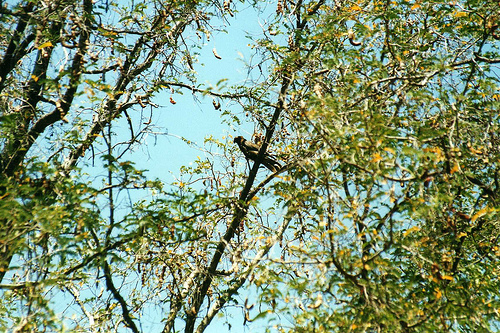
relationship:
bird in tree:
[233, 135, 283, 172] [3, 0, 497, 331]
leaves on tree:
[0, 0, 499, 333] [30, 25, 362, 324]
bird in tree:
[233, 135, 283, 172] [7, 38, 498, 327]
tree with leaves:
[3, 0, 497, 331] [318, 22, 363, 61]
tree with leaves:
[3, 0, 497, 331] [357, 106, 413, 158]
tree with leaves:
[3, 0, 497, 331] [277, 185, 346, 255]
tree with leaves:
[3, 0, 497, 331] [103, 150, 168, 191]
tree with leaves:
[3, 0, 497, 331] [131, 246, 205, 298]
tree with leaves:
[0, 0, 499, 333] [296, 100, 422, 202]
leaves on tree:
[51, 72, 436, 254] [3, 0, 497, 331]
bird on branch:
[233, 135, 283, 172] [181, 1, 312, 331]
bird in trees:
[233, 135, 283, 172] [4, 0, 498, 330]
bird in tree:
[233, 135, 283, 172] [117, 14, 347, 332]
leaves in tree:
[0, 0, 499, 333] [3, 0, 497, 331]